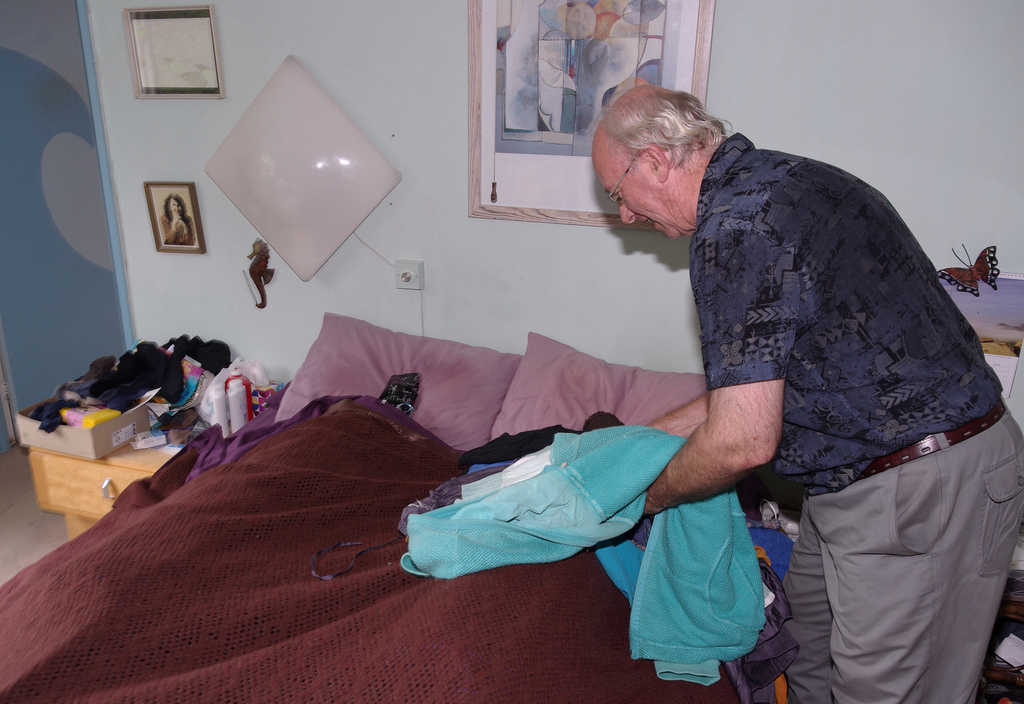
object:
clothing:
[685, 133, 1021, 703]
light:
[202, 55, 404, 282]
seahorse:
[247, 239, 275, 310]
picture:
[463, 0, 718, 227]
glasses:
[607, 157, 635, 202]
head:
[591, 86, 726, 239]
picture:
[466, 0, 716, 221]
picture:
[128, 3, 226, 100]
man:
[592, 88, 1021, 702]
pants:
[783, 401, 1021, 704]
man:
[589, 84, 1022, 702]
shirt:
[685, 133, 1003, 491]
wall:
[79, 0, 1023, 388]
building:
[0, 0, 1021, 692]